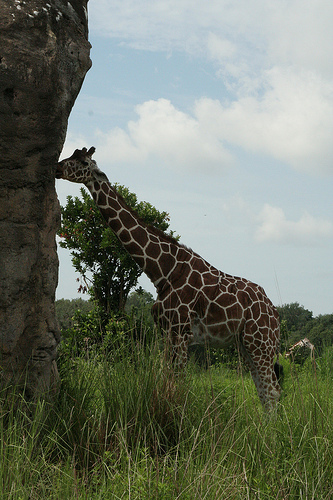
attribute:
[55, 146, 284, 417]
giraffe — eating, patterned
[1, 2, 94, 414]
wall — gray, tall, rock, wet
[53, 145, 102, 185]
head — up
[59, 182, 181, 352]
tree — green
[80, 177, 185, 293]
neck — long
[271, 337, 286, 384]
tail — short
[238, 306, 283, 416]
hind leg — long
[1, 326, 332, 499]
grass — tall, green, here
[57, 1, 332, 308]
sky — hazy, cloudy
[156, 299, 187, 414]
leg — long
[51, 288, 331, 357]
trees — green, farther away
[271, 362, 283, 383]
hair — black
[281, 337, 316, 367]
wood — worn